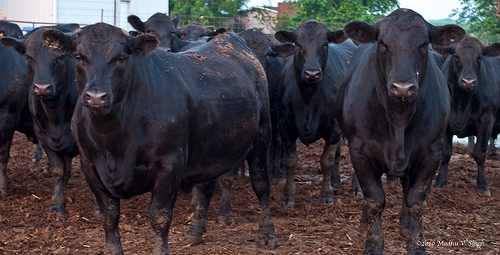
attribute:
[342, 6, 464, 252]
cow is black — are brown, big, large, dirty, female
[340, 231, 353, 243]
wooden chip — are wooden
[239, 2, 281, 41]
building — white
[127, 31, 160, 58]
ear of cow — extended, round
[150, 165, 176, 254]
front leg — dirty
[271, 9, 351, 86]
head of cow — black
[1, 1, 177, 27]
wall of a building — blue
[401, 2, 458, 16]
sky is bright — blue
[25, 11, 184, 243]
cow — black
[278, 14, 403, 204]
cow — black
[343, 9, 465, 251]
cow — black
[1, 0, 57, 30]
door — white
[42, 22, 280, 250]
cow — black